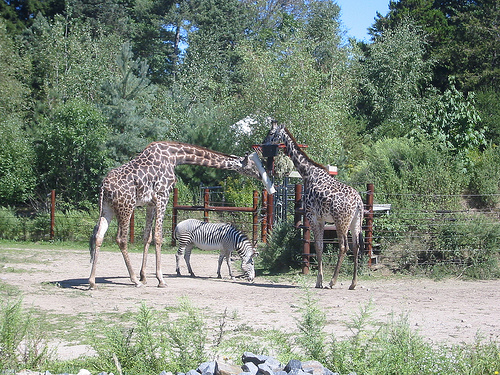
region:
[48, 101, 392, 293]
plenty animals are eating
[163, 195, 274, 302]
a black and white zebra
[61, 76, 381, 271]
2 giraffes and a zebra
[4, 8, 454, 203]
tall trees behind the animals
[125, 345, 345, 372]
a pile of rocks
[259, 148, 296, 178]
a feeder for the giraffes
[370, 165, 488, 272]
a wire fence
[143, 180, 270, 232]
brown poles holding up the wire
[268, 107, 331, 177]
the giraffes mane is brown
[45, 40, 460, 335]
its a sunny day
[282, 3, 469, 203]
the leaves are green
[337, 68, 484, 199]
The trees are leafy.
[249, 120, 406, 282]
The giraffe is tall.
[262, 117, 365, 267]
The giraffe is brown and tan.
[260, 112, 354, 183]
The mane is brown.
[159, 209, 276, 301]
The zebra is black and white.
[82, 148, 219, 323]
He is walking.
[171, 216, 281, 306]
The zebra is grazing.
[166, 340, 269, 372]
The rocks are grey.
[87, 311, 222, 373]
The grass is growing.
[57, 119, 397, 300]
Three animals are standing.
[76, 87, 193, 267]
the giraffe is brown and white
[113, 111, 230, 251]
the giraffe is brown and white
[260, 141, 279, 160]
the bucket is black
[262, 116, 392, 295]
the giraffe is tall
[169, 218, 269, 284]
the zebra is eating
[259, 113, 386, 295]
the giraffe is eating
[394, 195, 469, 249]
the fence is metal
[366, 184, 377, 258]
the pole is brown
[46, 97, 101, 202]
the tree is small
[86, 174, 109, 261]
the giraffe has a tail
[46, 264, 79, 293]
the shadow is on the ground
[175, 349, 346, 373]
the rocks are gray